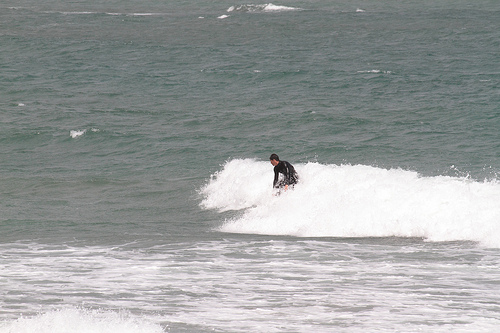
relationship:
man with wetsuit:
[264, 149, 301, 201] [274, 157, 298, 188]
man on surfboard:
[264, 149, 301, 201] [265, 185, 307, 200]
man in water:
[264, 149, 301, 201] [0, 0, 499, 333]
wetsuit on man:
[274, 157, 298, 188] [264, 149, 301, 201]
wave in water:
[1, 301, 171, 331] [0, 0, 499, 333]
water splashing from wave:
[200, 153, 499, 240] [198, 148, 500, 254]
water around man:
[200, 153, 499, 240] [264, 149, 301, 201]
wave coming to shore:
[1, 301, 171, 331] [4, 292, 499, 327]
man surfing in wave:
[264, 149, 301, 201] [198, 148, 500, 254]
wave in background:
[209, 0, 296, 19] [3, 4, 500, 151]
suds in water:
[7, 152, 499, 319] [0, 0, 499, 333]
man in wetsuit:
[264, 149, 301, 201] [274, 157, 298, 188]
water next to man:
[0, 0, 499, 333] [264, 149, 301, 201]